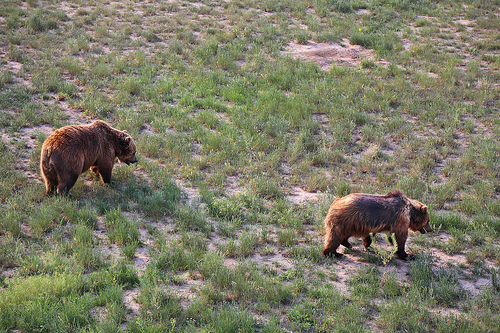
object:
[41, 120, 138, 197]
bear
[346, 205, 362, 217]
fur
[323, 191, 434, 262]
bear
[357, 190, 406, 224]
fur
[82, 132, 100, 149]
brown fur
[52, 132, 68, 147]
brown fur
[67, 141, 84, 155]
brown fur